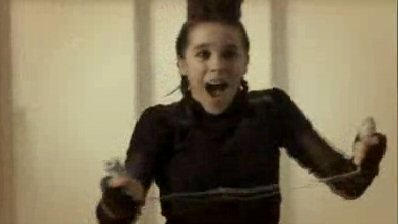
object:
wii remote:
[353, 115, 376, 160]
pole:
[360, 114, 375, 139]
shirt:
[96, 85, 378, 220]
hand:
[102, 168, 158, 203]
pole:
[100, 156, 127, 177]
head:
[178, 0, 244, 103]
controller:
[358, 117, 376, 134]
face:
[186, 28, 241, 104]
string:
[102, 168, 365, 202]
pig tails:
[185, 47, 249, 128]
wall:
[9, 11, 392, 216]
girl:
[94, 0, 385, 221]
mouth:
[204, 82, 232, 96]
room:
[2, 1, 395, 221]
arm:
[94, 100, 162, 222]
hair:
[173, 1, 247, 29]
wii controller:
[109, 154, 134, 198]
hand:
[350, 128, 385, 163]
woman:
[94, 2, 385, 220]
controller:
[102, 158, 128, 176]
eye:
[196, 52, 209, 54]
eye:
[226, 51, 236, 57]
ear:
[174, 55, 189, 76]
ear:
[244, 49, 249, 73]